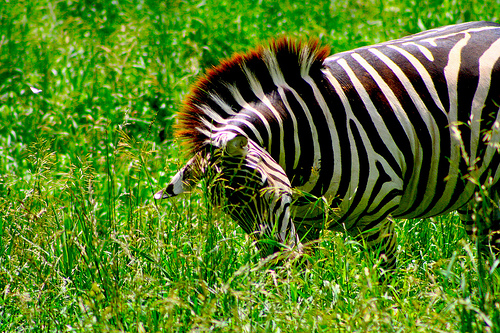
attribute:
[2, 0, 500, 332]
grass — here, green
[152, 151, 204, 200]
ear — black, white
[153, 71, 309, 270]
head — black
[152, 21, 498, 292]
zebra — here, black, white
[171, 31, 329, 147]
mane — brown, black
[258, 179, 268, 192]
eye — black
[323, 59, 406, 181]
stripe — black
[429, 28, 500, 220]
stripe — black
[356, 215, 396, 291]
leg — black, white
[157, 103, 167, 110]
flower — white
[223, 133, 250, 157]
ear — black, white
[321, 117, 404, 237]
shoulder — striped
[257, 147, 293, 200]
jaw — large